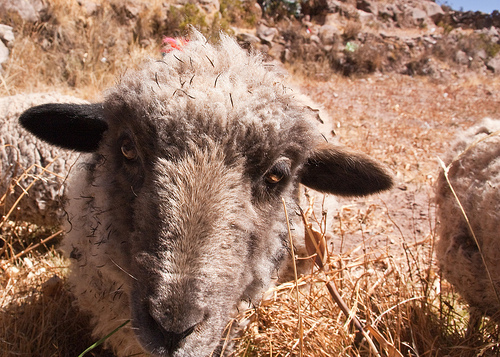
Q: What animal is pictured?
A: Sheep.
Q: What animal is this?
A: Sheep.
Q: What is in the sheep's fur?
A: Debris.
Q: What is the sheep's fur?
A: Fuzzy.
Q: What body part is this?
A: Ear.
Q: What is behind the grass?
A: Rocks.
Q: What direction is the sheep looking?
A: Forward.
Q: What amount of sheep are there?
A: 2.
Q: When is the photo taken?
A: During the day time.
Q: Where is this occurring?
A: Scene is outdoors.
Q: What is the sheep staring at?
A: Camera.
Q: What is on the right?
A: Part of another sheep.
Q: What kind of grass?
A: Dry.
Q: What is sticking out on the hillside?
A: Rocks.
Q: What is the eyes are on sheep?
A: Open.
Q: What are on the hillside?
A: Rocks.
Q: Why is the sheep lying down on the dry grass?
A: To rest.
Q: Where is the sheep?
A: A pasture.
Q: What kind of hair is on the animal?
A: Wool.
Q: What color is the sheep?
A: White.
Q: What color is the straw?
A: Yellow.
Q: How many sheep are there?
A: Three.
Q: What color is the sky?
A: Blue.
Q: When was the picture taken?
A: Daytime.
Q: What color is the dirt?
A: Brown.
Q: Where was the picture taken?
A: The wilderness.